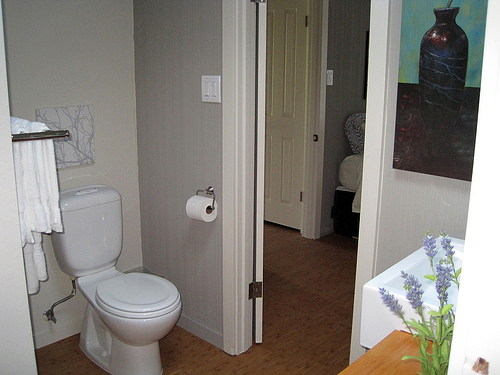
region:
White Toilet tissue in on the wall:
[166, 189, 226, 231]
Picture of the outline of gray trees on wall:
[31, 101, 117, 176]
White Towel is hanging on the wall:
[3, 108, 70, 260]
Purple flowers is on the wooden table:
[363, 228, 478, 373]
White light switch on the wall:
[191, 61, 227, 119]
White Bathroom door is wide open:
[217, 3, 370, 355]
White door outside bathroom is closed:
[258, 0, 328, 245]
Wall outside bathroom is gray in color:
[325, 4, 367, 246]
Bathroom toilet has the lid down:
[53, 186, 195, 373]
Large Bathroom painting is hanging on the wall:
[395, 1, 499, 209]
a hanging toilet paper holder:
[171, 170, 226, 241]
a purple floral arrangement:
[371, 222, 481, 374]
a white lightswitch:
[183, 55, 231, 119]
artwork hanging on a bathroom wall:
[392, 2, 484, 194]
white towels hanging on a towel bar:
[10, 107, 80, 309]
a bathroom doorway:
[202, 1, 414, 373]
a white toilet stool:
[44, 172, 205, 374]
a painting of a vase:
[401, 2, 483, 159]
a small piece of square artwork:
[29, 97, 112, 177]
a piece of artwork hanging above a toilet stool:
[31, 97, 187, 370]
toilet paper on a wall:
[178, 177, 221, 229]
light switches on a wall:
[193, 68, 223, 113]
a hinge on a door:
[239, 268, 269, 311]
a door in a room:
[262, 0, 332, 247]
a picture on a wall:
[363, 1, 496, 216]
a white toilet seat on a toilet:
[91, 265, 188, 327]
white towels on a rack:
[6, 115, 66, 301]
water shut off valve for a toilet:
[35, 300, 67, 331]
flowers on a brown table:
[360, 212, 471, 373]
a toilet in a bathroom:
[38, 179, 188, 374]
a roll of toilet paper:
[180, 190, 217, 227]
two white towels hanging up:
[8, 107, 75, 302]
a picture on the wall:
[394, 5, 495, 197]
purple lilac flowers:
[373, 230, 457, 373]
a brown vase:
[412, 4, 472, 149]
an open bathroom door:
[241, 5, 390, 347]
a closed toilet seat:
[86, 270, 181, 325]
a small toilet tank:
[47, 180, 132, 278]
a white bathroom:
[5, 11, 450, 371]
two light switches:
[198, 72, 223, 106]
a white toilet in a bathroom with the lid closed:
[42, 186, 190, 374]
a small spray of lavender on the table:
[372, 223, 452, 374]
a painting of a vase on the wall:
[399, 0, 469, 190]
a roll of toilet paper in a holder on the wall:
[182, 186, 227, 226]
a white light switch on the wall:
[195, 72, 224, 105]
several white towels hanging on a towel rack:
[3, 114, 75, 296]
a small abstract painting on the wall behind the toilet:
[31, 106, 101, 171]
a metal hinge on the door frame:
[242, 276, 267, 306]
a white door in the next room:
[262, 3, 312, 236]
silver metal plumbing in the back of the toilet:
[41, 281, 79, 328]